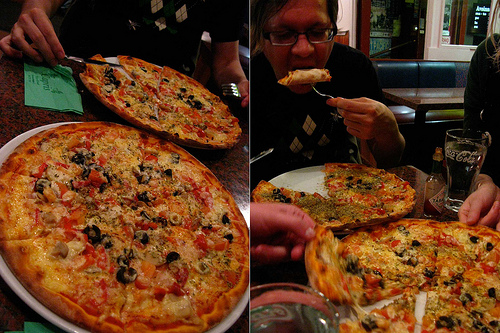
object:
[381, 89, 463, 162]
table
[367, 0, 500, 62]
window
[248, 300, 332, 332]
water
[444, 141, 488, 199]
water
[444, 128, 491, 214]
glass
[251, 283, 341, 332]
glass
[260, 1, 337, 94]
face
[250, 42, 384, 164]
sweater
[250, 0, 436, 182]
person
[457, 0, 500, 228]
person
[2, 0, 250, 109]
person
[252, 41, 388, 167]
shirt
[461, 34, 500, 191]
shirt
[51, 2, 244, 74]
shirt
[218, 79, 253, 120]
fork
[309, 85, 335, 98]
fork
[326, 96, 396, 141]
hand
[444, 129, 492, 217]
cup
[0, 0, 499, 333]
photos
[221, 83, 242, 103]
phone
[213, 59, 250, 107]
hand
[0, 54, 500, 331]
pizza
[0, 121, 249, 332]
white plate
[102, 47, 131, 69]
white plate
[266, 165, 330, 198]
white plate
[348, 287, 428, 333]
white plate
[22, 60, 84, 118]
napkin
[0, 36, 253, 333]
table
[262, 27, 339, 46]
eyeglasses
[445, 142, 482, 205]
dark liquid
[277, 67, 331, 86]
slice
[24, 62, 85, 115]
envelope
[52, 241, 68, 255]
sausage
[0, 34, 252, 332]
surface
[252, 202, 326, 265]
fingers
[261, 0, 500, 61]
background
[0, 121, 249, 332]
slices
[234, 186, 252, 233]
reflection